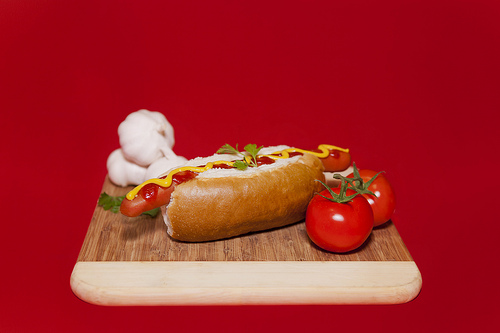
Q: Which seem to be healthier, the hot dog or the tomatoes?
A: The tomatoes are healthier than the hot dog.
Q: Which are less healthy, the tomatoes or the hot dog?
A: The hot dog are less healthy than the tomatoes.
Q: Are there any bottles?
A: No, there are no bottles.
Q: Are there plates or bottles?
A: No, there are no bottles or plates.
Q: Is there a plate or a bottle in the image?
A: No, there are no bottles or plates.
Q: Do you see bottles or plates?
A: No, there are no bottles or plates.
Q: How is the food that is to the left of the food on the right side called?
A: The food is a bun.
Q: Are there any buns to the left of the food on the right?
A: Yes, there is a bun to the left of the food.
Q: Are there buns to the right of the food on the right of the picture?
A: No, the bun is to the left of the food.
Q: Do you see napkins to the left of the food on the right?
A: No, there is a bun to the left of the food.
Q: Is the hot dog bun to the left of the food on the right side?
A: Yes, the bun is to the left of the food.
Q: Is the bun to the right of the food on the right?
A: No, the bun is to the left of the food.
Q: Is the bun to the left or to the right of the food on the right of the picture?
A: The bun is to the left of the food.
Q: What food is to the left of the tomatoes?
A: The food is a bun.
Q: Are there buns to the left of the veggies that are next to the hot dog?
A: Yes, there is a bun to the left of the tomatoes.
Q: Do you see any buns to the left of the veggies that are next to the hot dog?
A: Yes, there is a bun to the left of the tomatoes.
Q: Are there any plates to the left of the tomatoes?
A: No, there is a bun to the left of the tomatoes.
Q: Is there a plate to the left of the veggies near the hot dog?
A: No, there is a bun to the left of the tomatoes.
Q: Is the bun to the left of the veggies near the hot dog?
A: Yes, the bun is to the left of the tomatoes.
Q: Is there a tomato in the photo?
A: Yes, there are tomatoes.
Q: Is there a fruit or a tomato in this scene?
A: Yes, there are tomatoes.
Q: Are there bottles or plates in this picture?
A: No, there are no bottles or plates.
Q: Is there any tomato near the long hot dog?
A: Yes, there are tomatoes near the hot dog.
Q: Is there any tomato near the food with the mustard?
A: Yes, there are tomatoes near the hot dog.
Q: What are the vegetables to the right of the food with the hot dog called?
A: The vegetables are tomatoes.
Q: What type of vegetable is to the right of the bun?
A: The vegetables are tomatoes.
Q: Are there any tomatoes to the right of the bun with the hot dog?
A: Yes, there are tomatoes to the right of the bun.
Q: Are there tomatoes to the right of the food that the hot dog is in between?
A: Yes, there are tomatoes to the right of the bun.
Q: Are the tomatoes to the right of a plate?
A: No, the tomatoes are to the right of the bun.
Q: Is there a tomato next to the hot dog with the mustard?
A: Yes, there are tomatoes next to the hot dog.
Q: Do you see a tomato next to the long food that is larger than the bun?
A: Yes, there are tomatoes next to the hot dog.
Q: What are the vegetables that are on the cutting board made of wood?
A: The vegetables are tomatoes.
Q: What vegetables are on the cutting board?
A: The vegetables are tomatoes.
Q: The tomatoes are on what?
A: The tomatoes are on the cutting board.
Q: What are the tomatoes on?
A: The tomatoes are on the cutting board.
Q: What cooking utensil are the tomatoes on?
A: The tomatoes are on the cutting board.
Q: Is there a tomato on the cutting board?
A: Yes, there are tomatoes on the cutting board.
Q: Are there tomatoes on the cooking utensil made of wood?
A: Yes, there are tomatoes on the cutting board.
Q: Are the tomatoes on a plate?
A: No, the tomatoes are on the cutting board.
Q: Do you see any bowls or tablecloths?
A: No, there are no bowls or tablecloths.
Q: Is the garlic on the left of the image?
A: Yes, the garlic is on the left of the image.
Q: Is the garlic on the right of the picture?
A: No, the garlic is on the left of the image.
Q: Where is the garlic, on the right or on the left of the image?
A: The garlic is on the left of the image.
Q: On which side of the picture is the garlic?
A: The garlic is on the left of the image.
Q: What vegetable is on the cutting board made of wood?
A: The vegetable is garlic.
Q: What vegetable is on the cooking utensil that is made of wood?
A: The vegetable is garlic.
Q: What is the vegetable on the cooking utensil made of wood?
A: The vegetable is garlic.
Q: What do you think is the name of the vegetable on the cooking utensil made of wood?
A: The vegetable is garlic.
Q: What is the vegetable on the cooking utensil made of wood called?
A: The vegetable is garlic.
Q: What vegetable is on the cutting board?
A: The vegetable is garlic.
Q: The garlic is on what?
A: The garlic is on the cutting board.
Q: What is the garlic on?
A: The garlic is on the cutting board.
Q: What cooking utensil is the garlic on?
A: The garlic is on the cutting board.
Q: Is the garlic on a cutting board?
A: Yes, the garlic is on a cutting board.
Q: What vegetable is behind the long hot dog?
A: The vegetable is garlic.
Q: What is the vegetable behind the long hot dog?
A: The vegetable is garlic.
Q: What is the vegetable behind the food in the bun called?
A: The vegetable is garlic.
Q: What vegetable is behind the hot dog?
A: The vegetable is garlic.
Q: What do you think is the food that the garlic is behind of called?
A: The food is a hot dog.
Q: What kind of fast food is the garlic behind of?
A: The garlic is behind the hot dog.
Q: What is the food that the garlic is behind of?
A: The food is a hot dog.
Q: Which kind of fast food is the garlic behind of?
A: The garlic is behind the hot dog.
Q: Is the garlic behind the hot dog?
A: Yes, the garlic is behind the hot dog.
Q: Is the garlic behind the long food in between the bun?
A: Yes, the garlic is behind the hot dog.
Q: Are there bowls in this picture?
A: No, there are no bowls.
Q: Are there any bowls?
A: No, there are no bowls.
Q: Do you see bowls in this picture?
A: No, there are no bowls.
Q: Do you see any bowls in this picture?
A: No, there are no bowls.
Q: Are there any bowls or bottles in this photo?
A: No, there are no bowls or bottles.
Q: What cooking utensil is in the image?
A: The cooking utensil is a cutting board.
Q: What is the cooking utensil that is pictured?
A: The cooking utensil is a cutting board.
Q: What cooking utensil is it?
A: The cooking utensil is a cutting board.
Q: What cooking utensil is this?
A: That is a cutting board.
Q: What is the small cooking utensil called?
A: The cooking utensil is a cutting board.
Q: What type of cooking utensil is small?
A: The cooking utensil is a cutting board.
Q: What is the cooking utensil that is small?
A: The cooking utensil is a cutting board.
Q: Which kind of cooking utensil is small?
A: The cooking utensil is a cutting board.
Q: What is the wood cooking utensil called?
A: The cooking utensil is a cutting board.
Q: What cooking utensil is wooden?
A: The cooking utensil is a cutting board.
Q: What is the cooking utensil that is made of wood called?
A: The cooking utensil is a cutting board.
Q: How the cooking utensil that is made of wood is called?
A: The cooking utensil is a cutting board.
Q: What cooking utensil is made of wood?
A: The cooking utensil is a cutting board.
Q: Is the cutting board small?
A: Yes, the cutting board is small.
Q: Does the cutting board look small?
A: Yes, the cutting board is small.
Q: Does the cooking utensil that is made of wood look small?
A: Yes, the cutting board is small.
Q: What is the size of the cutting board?
A: The cutting board is small.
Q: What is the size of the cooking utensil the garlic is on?
A: The cutting board is small.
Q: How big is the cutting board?
A: The cutting board is small.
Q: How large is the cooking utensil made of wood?
A: The cutting board is small.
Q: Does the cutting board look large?
A: No, the cutting board is small.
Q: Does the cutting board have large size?
A: No, the cutting board is small.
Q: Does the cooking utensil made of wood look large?
A: No, the cutting board is small.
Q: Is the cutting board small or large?
A: The cutting board is small.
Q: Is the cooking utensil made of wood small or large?
A: The cutting board is small.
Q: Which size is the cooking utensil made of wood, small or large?
A: The cutting board is small.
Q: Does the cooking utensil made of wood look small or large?
A: The cutting board is small.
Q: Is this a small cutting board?
A: Yes, this is a small cutting board.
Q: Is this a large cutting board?
A: No, this is a small cutting board.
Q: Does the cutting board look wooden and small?
A: Yes, the cutting board is wooden and small.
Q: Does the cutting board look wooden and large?
A: No, the cutting board is wooden but small.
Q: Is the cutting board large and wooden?
A: No, the cutting board is wooden but small.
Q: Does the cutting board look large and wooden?
A: No, the cutting board is wooden but small.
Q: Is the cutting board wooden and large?
A: No, the cutting board is wooden but small.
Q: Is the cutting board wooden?
A: Yes, the cutting board is wooden.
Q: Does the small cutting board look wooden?
A: Yes, the cutting board is wooden.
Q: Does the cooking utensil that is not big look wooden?
A: Yes, the cutting board is wooden.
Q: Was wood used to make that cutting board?
A: Yes, the cutting board is made of wood.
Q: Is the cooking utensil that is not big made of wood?
A: Yes, the cutting board is made of wood.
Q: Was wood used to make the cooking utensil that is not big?
A: Yes, the cutting board is made of wood.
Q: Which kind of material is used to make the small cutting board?
A: The cutting board is made of wood.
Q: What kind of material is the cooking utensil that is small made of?
A: The cutting board is made of wood.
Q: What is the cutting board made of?
A: The cutting board is made of wood.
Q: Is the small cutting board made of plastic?
A: No, the cutting board is made of wood.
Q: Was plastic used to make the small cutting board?
A: No, the cutting board is made of wood.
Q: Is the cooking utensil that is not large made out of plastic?
A: No, the cutting board is made of wood.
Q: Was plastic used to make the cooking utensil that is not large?
A: No, the cutting board is made of wood.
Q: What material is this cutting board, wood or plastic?
A: The cutting board is made of wood.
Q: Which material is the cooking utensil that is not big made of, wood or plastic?
A: The cutting board is made of wood.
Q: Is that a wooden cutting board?
A: Yes, that is a wooden cutting board.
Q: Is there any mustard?
A: Yes, there is mustard.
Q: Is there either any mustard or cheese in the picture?
A: Yes, there is mustard.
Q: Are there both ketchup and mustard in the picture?
A: Yes, there are both mustard and ketchup.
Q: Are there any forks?
A: No, there are no forks.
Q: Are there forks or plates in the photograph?
A: No, there are no forks or plates.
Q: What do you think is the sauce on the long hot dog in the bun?
A: The sauce is mustard.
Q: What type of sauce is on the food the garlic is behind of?
A: The sauce is mustard.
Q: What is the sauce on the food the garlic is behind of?
A: The sauce is mustard.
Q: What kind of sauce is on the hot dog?
A: The sauce is mustard.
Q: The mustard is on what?
A: The mustard is on the hot dog.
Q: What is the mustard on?
A: The mustard is on the hot dog.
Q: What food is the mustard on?
A: The mustard is on the hot dog.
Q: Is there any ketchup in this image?
A: Yes, there is ketchup.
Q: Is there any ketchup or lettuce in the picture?
A: Yes, there is ketchup.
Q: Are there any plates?
A: No, there are no plates.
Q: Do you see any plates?
A: No, there are no plates.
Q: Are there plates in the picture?
A: No, there are no plates.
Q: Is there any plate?
A: No, there are no plates.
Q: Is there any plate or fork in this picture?
A: No, there are no plates or forks.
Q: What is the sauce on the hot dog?
A: The sauce is ketchup.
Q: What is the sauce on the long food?
A: The sauce is ketchup.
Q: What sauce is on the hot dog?
A: The sauce is ketchup.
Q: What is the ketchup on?
A: The ketchup is on the hot dog.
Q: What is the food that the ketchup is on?
A: The food is a hot dog.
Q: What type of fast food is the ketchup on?
A: The ketchup is on the hot dog.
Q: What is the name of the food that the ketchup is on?
A: The food is a hot dog.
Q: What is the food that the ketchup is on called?
A: The food is a hot dog.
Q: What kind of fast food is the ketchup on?
A: The ketchup is on the hot dog.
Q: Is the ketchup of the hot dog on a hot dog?
A: Yes, the ketchup is on a hot dog.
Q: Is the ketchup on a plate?
A: No, the ketchup is on a hot dog.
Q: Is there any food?
A: Yes, there is food.